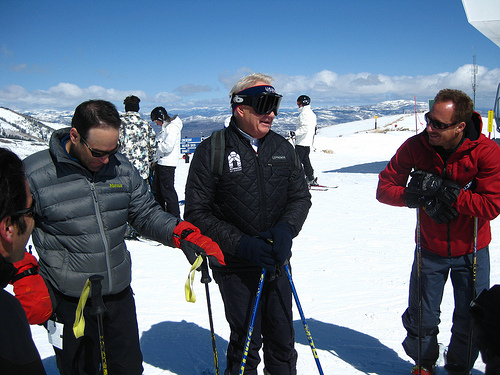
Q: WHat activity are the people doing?
A: Skiing.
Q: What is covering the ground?
A: Snow.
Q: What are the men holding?
A: Ski poles.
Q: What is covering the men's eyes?
A: Sunglasses.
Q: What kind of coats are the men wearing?
A: Ski jackets.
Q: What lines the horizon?
A: Mountains.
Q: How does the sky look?
A: Partly cloudy and bright.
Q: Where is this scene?
A: On a snowy mountain.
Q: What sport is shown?
A: Skiing.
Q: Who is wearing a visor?
A: The man in the black outfit.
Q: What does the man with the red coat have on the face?
A: Sunglasses.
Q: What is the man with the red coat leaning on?
A: Ski poles.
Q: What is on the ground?
A: Snow.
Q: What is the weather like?
A: Sunny with blue skies and white clouds.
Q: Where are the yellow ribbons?
A: At the top of the ski poles.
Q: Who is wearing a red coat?
A: The man on the mountain.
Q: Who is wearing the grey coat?
A: The man on the snowy mountain.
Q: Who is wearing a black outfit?
A: The man with the visor.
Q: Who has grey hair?
A: The man wearing the visor.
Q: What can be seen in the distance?
A: Mountain ranges.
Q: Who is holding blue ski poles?
A: The man in the black outfit.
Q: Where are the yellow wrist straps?
A: At the top of the ski poles.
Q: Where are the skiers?
A: On the snowy slope.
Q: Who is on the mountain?
A: Skiers.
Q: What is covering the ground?
A: Snow.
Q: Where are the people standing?
A: In the snow.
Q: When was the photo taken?
A: Daytime.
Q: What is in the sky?
A: Clouds.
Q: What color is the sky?
A: Blue.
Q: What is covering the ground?
A: Snow.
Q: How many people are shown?
A: Seven.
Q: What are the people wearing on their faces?
A: Sunglasses.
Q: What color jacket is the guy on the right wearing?
A: Orange.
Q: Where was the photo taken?
A: At a ski resort.